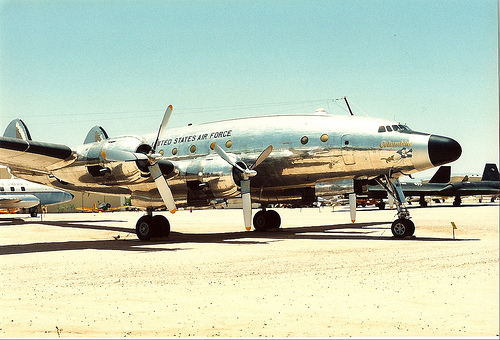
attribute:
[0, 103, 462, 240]
plane — old, air force, antique, retired, silver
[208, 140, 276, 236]
propeller — small, big, inside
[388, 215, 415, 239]
wheel — black, stopped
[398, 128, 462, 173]
nose — black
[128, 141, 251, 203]
engine — twin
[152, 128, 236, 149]
writing — united states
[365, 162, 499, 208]
jet — black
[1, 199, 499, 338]
runway — dirt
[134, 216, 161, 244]
back wheel — right side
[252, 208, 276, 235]
back wheel — left side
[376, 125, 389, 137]
window — pilots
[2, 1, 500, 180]
sky — blue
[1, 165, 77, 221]
airplane — partial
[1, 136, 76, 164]
edge — black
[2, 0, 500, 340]
picture — airplane